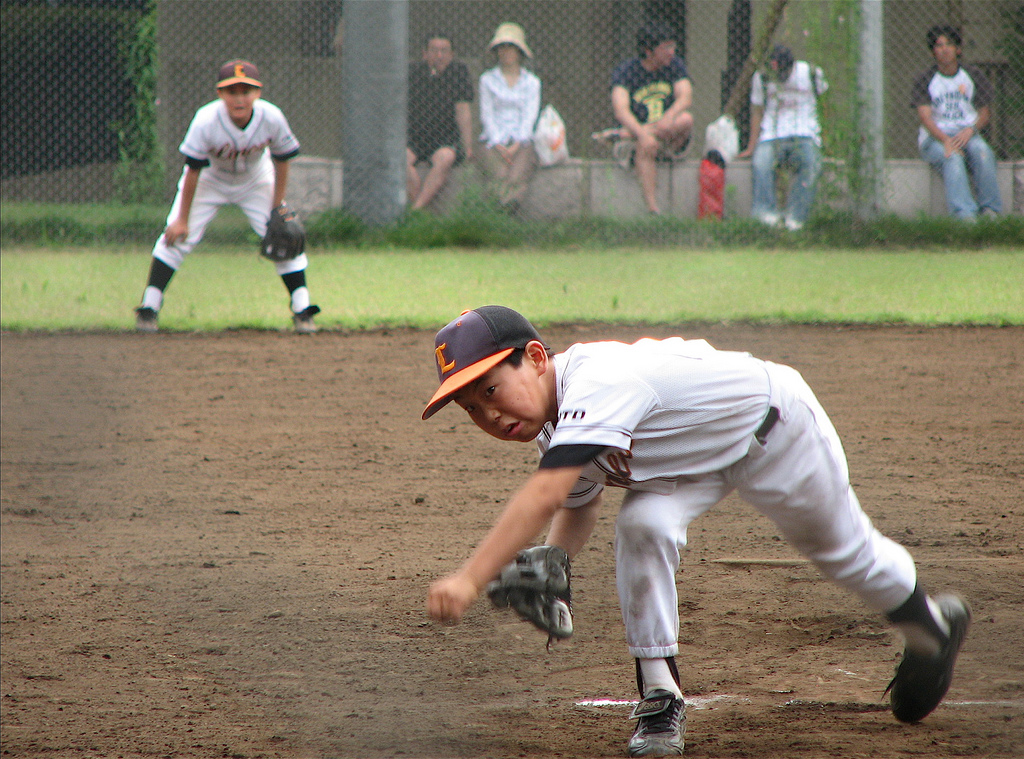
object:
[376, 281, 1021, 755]
boy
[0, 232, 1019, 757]
field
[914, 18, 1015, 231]
man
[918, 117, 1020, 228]
jeans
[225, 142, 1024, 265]
wall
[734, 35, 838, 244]
man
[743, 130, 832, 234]
jeans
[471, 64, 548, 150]
shirt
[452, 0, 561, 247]
woman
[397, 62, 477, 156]
shirt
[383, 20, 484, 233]
man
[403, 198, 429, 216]
ankles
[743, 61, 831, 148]
shirt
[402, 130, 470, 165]
shorts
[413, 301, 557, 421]
hat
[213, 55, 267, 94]
hat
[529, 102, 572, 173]
bag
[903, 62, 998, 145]
shirt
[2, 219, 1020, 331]
grass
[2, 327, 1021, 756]
dirt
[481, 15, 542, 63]
hat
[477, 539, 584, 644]
glove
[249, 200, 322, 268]
glove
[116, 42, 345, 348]
boy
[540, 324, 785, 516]
jersey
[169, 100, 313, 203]
jersey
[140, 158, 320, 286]
pants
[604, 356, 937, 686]
pants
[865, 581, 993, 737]
shoes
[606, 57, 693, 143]
shirt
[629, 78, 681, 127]
logo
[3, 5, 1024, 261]
fence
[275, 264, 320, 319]
socks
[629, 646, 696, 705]
socks